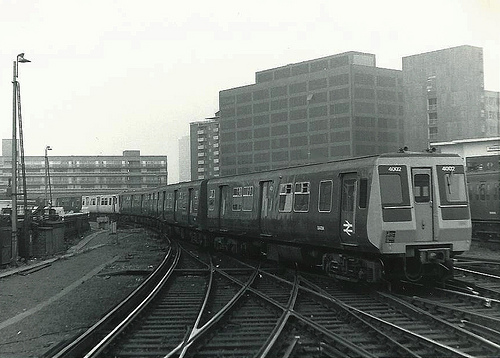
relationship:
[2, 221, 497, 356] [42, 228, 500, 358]
train yard has track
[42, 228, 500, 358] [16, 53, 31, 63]
track have a instrument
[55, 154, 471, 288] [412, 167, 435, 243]
train has a door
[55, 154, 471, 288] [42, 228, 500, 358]
train on track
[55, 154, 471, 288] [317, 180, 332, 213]
train has a window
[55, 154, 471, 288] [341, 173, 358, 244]
train has a backdoor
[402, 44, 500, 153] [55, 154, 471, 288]
building behind train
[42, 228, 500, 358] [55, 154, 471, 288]
track have a train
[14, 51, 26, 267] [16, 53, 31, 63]
pole has a instrument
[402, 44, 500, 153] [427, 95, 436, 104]
building has a window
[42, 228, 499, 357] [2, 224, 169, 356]
track has gravel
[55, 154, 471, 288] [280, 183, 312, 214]
train for passengers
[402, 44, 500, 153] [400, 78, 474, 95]
building has multi stories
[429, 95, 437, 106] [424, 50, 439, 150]
porches are in a row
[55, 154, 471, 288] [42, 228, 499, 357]
train has a track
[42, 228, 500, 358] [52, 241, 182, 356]
track have rails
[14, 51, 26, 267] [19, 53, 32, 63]
pole has a instrument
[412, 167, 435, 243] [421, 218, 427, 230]
door has a symbol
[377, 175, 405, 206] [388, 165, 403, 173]
window have numbers